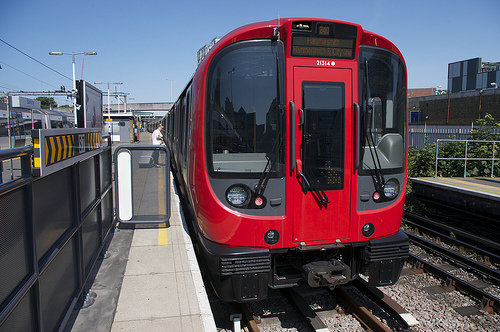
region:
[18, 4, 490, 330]
A train sitting on tracks.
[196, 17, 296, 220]
Front windshield of train.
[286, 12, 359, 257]
Door on train.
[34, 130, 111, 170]
Yellow and black sign.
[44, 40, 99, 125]
A utility pole.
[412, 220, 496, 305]
A set of train tracks.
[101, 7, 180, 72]
A patch of blue sky.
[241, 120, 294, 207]
Windshield wiper on train.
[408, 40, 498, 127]
A red building in the background.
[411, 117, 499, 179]
Green shrubbery on right side picture.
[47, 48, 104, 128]
Streetlight to the left of the train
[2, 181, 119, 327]
Wall to the left of the train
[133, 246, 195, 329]
Sidewalk to the left of the train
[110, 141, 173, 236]
Gate to the left of the train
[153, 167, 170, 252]
Yellow stripe on the ground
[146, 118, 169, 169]
Person waiting to get on the train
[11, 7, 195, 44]
Bright blue sky behind the train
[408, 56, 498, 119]
Buildings to the right of the train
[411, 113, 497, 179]
Bushes to the right of the train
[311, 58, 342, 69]
Small numbers on the front of the train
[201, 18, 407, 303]
Front of a red train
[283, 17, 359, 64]
The destination sign on a train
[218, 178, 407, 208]
Lights on the front of the train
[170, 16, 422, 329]
A train at a platform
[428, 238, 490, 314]
Train track with rust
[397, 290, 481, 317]
Gravel in between train tracks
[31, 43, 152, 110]
Overhead lights on a train platform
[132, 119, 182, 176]
A person boarding a train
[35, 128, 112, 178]
Black and gold reflector sign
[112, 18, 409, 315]
A long train at an uncrowded platform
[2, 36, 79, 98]
Utility wires in the sky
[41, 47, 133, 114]
Utility poles next to the train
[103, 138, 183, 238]
Gate next to the train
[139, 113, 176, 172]
Boarder waiting to get on the train.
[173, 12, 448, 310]
Red train on the tracks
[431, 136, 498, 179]
Fence to the right of the train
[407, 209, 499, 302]
Empty set of train tracks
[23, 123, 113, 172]
Yellow and gray sign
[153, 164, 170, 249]
Yellow paint on walkway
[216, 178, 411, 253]
Lights on the front of the train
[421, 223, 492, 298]
Rail lines for train.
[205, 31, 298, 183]
Large window of train.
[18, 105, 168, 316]
A security gate.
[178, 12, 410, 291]
A red and black commuter train.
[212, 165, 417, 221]
A trains headlights.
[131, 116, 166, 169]
A person with bags about to board a train.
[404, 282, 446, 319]
A gravel base for laying tracks.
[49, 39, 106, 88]
A light pole.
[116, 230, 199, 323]
A sidewalk bordering train tracks.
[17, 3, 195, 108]
A cloudless sky.